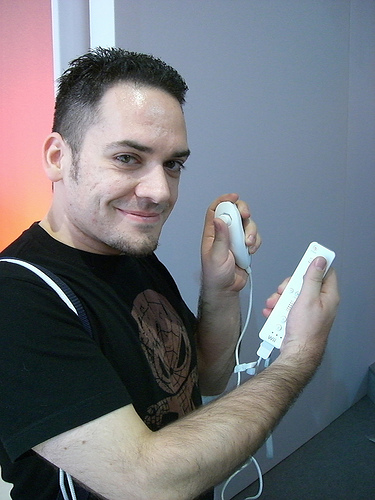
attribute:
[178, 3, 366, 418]
wall — blue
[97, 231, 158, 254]
beard — small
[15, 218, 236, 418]
shirt — black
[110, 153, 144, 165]
eye — brown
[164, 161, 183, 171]
eye — brown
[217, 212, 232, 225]
button — small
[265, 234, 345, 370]
remote — white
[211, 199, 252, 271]
controllers — white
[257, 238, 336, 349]
controllers — white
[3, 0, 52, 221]
wall — pink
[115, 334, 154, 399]
shirt — black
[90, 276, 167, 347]
tee shirt — black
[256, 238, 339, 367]
controller — white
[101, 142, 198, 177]
eyes — brown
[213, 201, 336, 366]
wii remote — white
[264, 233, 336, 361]
wii controller — white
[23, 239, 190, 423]
shirt — black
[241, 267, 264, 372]
cord — white